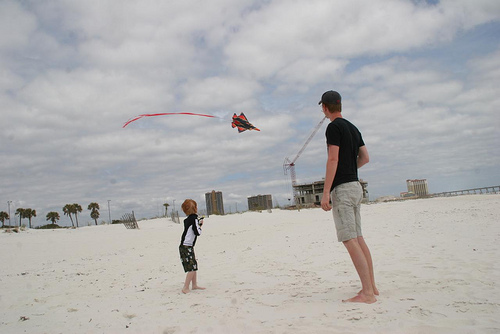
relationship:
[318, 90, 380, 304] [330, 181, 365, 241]
man wearing shorts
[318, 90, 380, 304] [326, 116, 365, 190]
man wearing shirt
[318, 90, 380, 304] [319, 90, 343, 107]
man wearing hat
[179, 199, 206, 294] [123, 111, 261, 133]
boy flying a kite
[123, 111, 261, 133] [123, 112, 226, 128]
kite has a tail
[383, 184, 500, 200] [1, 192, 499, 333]
pier near sand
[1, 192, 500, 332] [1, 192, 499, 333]
footprints in sand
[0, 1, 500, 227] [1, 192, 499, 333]
sky above sand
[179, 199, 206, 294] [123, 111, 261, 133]
boy flying kite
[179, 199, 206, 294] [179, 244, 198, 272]
boy wearing shorts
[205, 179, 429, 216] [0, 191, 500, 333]
buildings next to beach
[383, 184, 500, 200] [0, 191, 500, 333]
pier at beach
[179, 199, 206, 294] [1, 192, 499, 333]
boy standing on sand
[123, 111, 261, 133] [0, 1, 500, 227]
kite in sky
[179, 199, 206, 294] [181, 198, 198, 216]
boy has hair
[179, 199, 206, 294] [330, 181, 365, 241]
boy wearing shorts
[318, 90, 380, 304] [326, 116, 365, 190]
man wearing a shirt